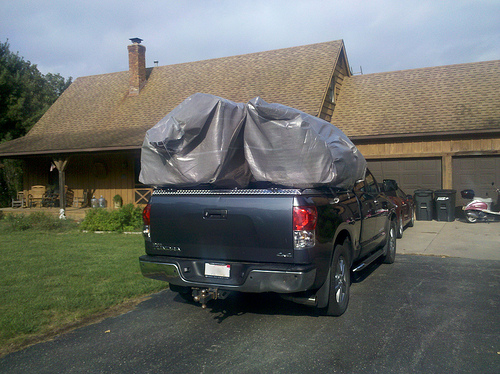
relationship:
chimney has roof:
[128, 37, 145, 92] [0, 39, 352, 153]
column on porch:
[429, 139, 486, 203] [0, 160, 146, 223]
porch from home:
[0, 160, 146, 223] [2, 36, 493, 219]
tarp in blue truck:
[135, 92, 372, 189] [137, 92, 399, 316]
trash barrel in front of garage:
[411, 187, 435, 222] [335, 60, 497, 220]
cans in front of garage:
[433, 189, 456, 222] [335, 60, 497, 220]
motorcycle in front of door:
[459, 188, 500, 224] [368, 158, 442, 198]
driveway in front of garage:
[377, 228, 499, 354] [450, 151, 498, 207]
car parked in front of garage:
[373, 139, 429, 244] [365, 157, 442, 211]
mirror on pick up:
[383, 179, 399, 190] [134, 160, 403, 317]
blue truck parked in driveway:
[137, 92, 399, 316] [1, 209, 495, 371]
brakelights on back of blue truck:
[291, 204, 318, 249] [137, 92, 399, 316]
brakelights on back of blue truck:
[141, 200, 151, 242] [137, 92, 399, 316]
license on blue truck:
[205, 262, 232, 277] [137, 92, 399, 316]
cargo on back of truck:
[111, 81, 364, 208] [103, 100, 445, 324]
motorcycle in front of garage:
[455, 184, 495, 226] [335, 60, 497, 220]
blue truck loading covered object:
[137, 92, 399, 316] [138, 91, 369, 188]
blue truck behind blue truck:
[137, 92, 399, 316] [137, 92, 399, 316]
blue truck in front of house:
[137, 92, 399, 316] [3, 35, 498, 230]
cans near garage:
[431, 184, 456, 224] [335, 60, 497, 220]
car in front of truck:
[375, 182, 416, 238] [127, 85, 416, 323]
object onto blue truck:
[139, 91, 365, 191] [137, 92, 399, 316]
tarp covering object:
[135, 92, 372, 189] [139, 91, 365, 191]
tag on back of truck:
[198, 260, 236, 280] [134, 132, 398, 322]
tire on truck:
[321, 243, 352, 317] [111, 154, 422, 334]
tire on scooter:
[321, 235, 354, 315] [460, 191, 497, 223]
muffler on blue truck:
[284, 293, 317, 307] [137, 92, 399, 316]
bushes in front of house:
[77, 200, 139, 230] [8, 38, 498, 205]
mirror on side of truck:
[383, 178, 399, 191] [145, 167, 395, 313]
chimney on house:
[128, 37, 145, 92] [8, 38, 498, 205]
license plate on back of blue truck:
[202, 263, 233, 280] [125, 89, 402, 322]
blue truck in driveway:
[137, 92, 399, 316] [1, 209, 495, 371]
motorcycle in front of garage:
[459, 188, 500, 224] [335, 60, 497, 220]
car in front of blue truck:
[375, 182, 416, 238] [137, 92, 399, 316]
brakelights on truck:
[291, 204, 318, 249] [123, 145, 438, 332]